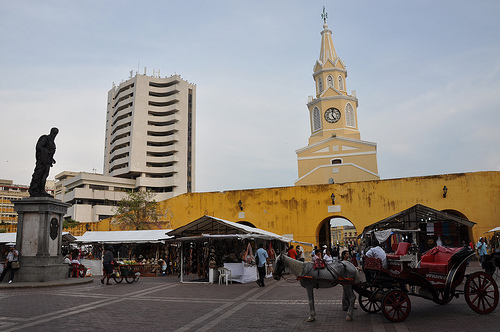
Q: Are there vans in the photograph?
A: No, there are no vans.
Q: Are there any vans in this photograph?
A: No, there are no vans.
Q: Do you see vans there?
A: No, there are no vans.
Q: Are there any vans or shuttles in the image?
A: No, there are no vans or shuttles.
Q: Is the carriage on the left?
A: No, the carriage is on the right of the image.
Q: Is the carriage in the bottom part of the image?
A: Yes, the carriage is in the bottom of the image.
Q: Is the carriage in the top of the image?
A: No, the carriage is in the bottom of the image.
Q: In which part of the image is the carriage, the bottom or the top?
A: The carriage is in the bottom of the image.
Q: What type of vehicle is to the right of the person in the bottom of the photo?
A: The vehicle is a carriage.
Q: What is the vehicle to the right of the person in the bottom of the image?
A: The vehicle is a carriage.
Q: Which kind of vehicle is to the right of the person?
A: The vehicle is a carriage.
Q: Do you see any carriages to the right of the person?
A: Yes, there is a carriage to the right of the person.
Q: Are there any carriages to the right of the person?
A: Yes, there is a carriage to the right of the person.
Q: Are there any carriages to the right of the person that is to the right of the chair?
A: Yes, there is a carriage to the right of the person.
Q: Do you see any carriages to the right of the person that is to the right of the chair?
A: Yes, there is a carriage to the right of the person.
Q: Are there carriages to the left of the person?
A: No, the carriage is to the right of the person.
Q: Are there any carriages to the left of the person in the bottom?
A: No, the carriage is to the right of the person.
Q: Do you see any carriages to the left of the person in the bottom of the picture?
A: No, the carriage is to the right of the person.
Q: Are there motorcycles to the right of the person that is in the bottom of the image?
A: No, there is a carriage to the right of the person.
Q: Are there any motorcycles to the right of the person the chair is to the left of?
A: No, there is a carriage to the right of the person.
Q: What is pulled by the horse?
A: The carriage is pulled by the horse.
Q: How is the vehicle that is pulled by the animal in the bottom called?
A: The vehicle is a carriage.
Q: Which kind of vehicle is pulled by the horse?
A: The vehicle is a carriage.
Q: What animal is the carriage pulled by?
A: The carriage is pulled by the horse.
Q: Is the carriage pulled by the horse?
A: Yes, the carriage is pulled by the horse.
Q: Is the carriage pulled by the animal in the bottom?
A: Yes, the carriage is pulled by the horse.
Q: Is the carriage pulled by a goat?
A: No, the carriage is pulled by the horse.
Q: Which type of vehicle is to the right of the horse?
A: The vehicle is a carriage.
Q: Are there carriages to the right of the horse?
A: Yes, there is a carriage to the right of the horse.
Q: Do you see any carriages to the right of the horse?
A: Yes, there is a carriage to the right of the horse.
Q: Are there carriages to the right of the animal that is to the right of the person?
A: Yes, there is a carriage to the right of the horse.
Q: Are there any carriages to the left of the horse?
A: No, the carriage is to the right of the horse.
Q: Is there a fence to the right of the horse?
A: No, there is a carriage to the right of the horse.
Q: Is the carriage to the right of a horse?
A: Yes, the carriage is to the right of a horse.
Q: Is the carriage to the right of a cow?
A: No, the carriage is to the right of a horse.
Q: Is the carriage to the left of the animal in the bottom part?
A: No, the carriage is to the right of the horse.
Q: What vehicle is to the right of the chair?
A: The vehicle is a carriage.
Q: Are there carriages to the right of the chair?
A: Yes, there is a carriage to the right of the chair.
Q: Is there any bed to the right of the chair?
A: No, there is a carriage to the right of the chair.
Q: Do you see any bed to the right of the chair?
A: No, there is a carriage to the right of the chair.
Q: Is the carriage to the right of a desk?
A: No, the carriage is to the right of the chair.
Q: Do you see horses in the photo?
A: Yes, there is a horse.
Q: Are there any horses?
A: Yes, there is a horse.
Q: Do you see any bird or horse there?
A: Yes, there is a horse.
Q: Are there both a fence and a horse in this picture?
A: No, there is a horse but no fences.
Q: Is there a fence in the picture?
A: No, there are no fences.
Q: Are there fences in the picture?
A: No, there are no fences.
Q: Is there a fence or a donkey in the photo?
A: No, there are no fences or donkeys.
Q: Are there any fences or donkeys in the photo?
A: No, there are no fences or donkeys.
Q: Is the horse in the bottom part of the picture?
A: Yes, the horse is in the bottom of the image.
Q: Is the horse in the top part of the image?
A: No, the horse is in the bottom of the image.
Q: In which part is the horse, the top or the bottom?
A: The horse is in the bottom of the image.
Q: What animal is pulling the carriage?
A: The horse is pulling the carriage.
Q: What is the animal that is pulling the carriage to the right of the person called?
A: The animal is a horse.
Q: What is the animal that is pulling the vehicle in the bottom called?
A: The animal is a horse.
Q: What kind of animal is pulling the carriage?
A: The animal is a horse.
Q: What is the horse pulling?
A: The horse is pulling the carriage.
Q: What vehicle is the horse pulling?
A: The horse is pulling the carriage.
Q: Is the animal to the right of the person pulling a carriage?
A: Yes, the horse is pulling a carriage.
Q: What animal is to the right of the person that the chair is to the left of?
A: The animal is a horse.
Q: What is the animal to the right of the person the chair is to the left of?
A: The animal is a horse.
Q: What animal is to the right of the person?
A: The animal is a horse.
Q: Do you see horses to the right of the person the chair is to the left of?
A: Yes, there is a horse to the right of the person.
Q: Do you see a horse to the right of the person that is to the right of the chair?
A: Yes, there is a horse to the right of the person.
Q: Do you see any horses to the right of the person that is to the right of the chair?
A: Yes, there is a horse to the right of the person.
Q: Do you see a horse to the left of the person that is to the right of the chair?
A: No, the horse is to the right of the person.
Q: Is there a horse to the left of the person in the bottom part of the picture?
A: No, the horse is to the right of the person.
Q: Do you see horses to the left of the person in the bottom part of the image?
A: No, the horse is to the right of the person.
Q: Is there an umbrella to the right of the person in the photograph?
A: No, there is a horse to the right of the person.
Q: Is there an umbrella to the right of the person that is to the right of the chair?
A: No, there is a horse to the right of the person.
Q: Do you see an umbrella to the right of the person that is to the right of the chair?
A: No, there is a horse to the right of the person.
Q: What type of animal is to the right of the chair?
A: The animal is a horse.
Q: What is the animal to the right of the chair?
A: The animal is a horse.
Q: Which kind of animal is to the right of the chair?
A: The animal is a horse.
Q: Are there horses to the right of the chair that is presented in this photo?
A: Yes, there is a horse to the right of the chair.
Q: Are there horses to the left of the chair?
A: No, the horse is to the right of the chair.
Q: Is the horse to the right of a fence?
A: No, the horse is to the right of the chair.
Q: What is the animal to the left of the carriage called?
A: The animal is a horse.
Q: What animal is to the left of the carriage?
A: The animal is a horse.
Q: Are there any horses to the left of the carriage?
A: Yes, there is a horse to the left of the carriage.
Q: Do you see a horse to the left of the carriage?
A: Yes, there is a horse to the left of the carriage.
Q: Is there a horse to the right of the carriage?
A: No, the horse is to the left of the carriage.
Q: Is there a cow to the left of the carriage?
A: No, there is a horse to the left of the carriage.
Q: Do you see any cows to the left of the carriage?
A: No, there is a horse to the left of the carriage.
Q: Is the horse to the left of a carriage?
A: Yes, the horse is to the left of a carriage.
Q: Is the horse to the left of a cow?
A: No, the horse is to the left of a carriage.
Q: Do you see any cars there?
A: No, there are no cars.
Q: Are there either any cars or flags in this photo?
A: No, there are no cars or flags.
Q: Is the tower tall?
A: Yes, the tower is tall.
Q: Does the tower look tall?
A: Yes, the tower is tall.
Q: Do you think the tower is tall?
A: Yes, the tower is tall.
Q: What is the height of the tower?
A: The tower is tall.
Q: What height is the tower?
A: The tower is tall.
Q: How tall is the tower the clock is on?
A: The tower is tall.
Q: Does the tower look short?
A: No, the tower is tall.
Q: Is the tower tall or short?
A: The tower is tall.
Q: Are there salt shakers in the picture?
A: No, there are no salt shakers.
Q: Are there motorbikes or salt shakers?
A: No, there are no salt shakers or motorbikes.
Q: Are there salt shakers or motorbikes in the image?
A: No, there are no salt shakers or motorbikes.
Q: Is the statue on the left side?
A: Yes, the statue is on the left of the image.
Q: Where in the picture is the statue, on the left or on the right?
A: The statue is on the left of the image.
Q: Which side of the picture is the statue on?
A: The statue is on the left of the image.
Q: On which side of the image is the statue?
A: The statue is on the left of the image.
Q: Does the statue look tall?
A: Yes, the statue is tall.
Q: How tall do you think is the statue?
A: The statue is tall.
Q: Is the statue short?
A: No, the statue is tall.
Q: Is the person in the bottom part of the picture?
A: Yes, the person is in the bottom of the image.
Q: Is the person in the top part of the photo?
A: No, the person is in the bottom of the image.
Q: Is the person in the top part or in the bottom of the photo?
A: The person is in the bottom of the image.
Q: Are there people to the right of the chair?
A: Yes, there is a person to the right of the chair.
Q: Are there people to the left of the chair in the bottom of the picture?
A: No, the person is to the right of the chair.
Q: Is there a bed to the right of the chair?
A: No, there is a person to the right of the chair.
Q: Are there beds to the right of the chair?
A: No, there is a person to the right of the chair.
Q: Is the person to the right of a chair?
A: Yes, the person is to the right of a chair.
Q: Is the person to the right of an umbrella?
A: No, the person is to the right of a chair.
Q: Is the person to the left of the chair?
A: No, the person is to the right of the chair.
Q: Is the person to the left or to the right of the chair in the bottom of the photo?
A: The person is to the right of the chair.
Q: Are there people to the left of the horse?
A: Yes, there is a person to the left of the horse.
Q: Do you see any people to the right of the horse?
A: No, the person is to the left of the horse.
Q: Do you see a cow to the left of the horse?
A: No, there is a person to the left of the horse.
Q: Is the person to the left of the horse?
A: Yes, the person is to the left of the horse.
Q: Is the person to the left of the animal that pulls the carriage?
A: Yes, the person is to the left of the horse.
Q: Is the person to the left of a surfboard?
A: No, the person is to the left of the horse.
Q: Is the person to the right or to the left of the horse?
A: The person is to the left of the horse.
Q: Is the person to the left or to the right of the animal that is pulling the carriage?
A: The person is to the left of the horse.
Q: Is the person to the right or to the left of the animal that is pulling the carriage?
A: The person is to the left of the horse.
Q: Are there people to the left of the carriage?
A: Yes, there is a person to the left of the carriage.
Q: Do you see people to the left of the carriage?
A: Yes, there is a person to the left of the carriage.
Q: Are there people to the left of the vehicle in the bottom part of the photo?
A: Yes, there is a person to the left of the carriage.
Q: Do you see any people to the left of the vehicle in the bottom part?
A: Yes, there is a person to the left of the carriage.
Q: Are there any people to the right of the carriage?
A: No, the person is to the left of the carriage.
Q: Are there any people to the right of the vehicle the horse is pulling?
A: No, the person is to the left of the carriage.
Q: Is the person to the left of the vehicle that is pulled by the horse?
A: Yes, the person is to the left of the carriage.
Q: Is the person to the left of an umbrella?
A: No, the person is to the left of the carriage.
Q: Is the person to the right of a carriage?
A: No, the person is to the left of a carriage.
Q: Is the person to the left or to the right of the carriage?
A: The person is to the left of the carriage.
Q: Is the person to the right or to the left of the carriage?
A: The person is to the left of the carriage.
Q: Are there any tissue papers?
A: No, there are no tissue papers.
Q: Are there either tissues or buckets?
A: No, there are no tissues or buckets.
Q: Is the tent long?
A: Yes, the tent is long.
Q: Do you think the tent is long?
A: Yes, the tent is long.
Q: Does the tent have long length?
A: Yes, the tent is long.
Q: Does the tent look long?
A: Yes, the tent is long.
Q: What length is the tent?
A: The tent is long.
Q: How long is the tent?
A: The tent is long.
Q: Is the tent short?
A: No, the tent is long.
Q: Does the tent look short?
A: No, the tent is long.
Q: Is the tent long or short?
A: The tent is long.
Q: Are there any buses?
A: No, there are no buses.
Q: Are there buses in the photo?
A: No, there are no buses.